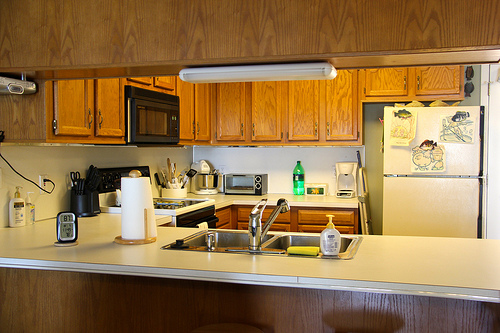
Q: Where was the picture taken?
A: It was taken at the kitchen.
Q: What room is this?
A: It is a kitchen.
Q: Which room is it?
A: It is a kitchen.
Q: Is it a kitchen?
A: Yes, it is a kitchen.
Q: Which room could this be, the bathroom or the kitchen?
A: It is the kitchen.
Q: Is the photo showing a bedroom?
A: No, the picture is showing a kitchen.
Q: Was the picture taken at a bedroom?
A: No, the picture was taken in a kitchen.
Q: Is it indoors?
A: Yes, it is indoors.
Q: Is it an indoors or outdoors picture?
A: It is indoors.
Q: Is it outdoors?
A: No, it is indoors.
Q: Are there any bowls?
A: No, there are no bowls.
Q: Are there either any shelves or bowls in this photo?
A: No, there are no bowls or shelves.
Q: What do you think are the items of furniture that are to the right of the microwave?
A: The pieces of furniture are cabinets.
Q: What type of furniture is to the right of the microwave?
A: The pieces of furniture are cabinets.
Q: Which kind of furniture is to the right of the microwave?
A: The pieces of furniture are cabinets.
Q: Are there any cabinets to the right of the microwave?
A: Yes, there are cabinets to the right of the microwave.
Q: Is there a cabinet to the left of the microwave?
A: No, the cabinets are to the right of the microwave.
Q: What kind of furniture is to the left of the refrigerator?
A: The pieces of furniture are cabinets.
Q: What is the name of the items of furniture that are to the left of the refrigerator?
A: The pieces of furniture are cabinets.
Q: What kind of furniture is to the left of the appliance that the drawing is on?
A: The pieces of furniture are cabinets.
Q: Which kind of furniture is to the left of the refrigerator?
A: The pieces of furniture are cabinets.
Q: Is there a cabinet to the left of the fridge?
A: Yes, there are cabinets to the left of the fridge.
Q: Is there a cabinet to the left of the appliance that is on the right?
A: Yes, there are cabinets to the left of the fridge.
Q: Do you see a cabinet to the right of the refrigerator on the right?
A: No, the cabinets are to the left of the fridge.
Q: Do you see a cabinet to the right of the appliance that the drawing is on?
A: No, the cabinets are to the left of the fridge.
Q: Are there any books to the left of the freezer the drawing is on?
A: No, there are cabinets to the left of the freezer.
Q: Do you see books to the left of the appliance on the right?
A: No, there are cabinets to the left of the freezer.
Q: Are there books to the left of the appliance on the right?
A: No, there are cabinets to the left of the freezer.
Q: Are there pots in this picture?
A: No, there are no pots.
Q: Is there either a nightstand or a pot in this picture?
A: No, there are no pots or nightstands.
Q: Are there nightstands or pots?
A: No, there are no pots or nightstands.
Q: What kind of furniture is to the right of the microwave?
A: The pieces of furniture are cabinets.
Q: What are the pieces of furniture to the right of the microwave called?
A: The pieces of furniture are cabinets.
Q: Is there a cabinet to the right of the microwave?
A: Yes, there are cabinets to the right of the microwave.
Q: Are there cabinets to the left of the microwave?
A: No, the cabinets are to the right of the microwave.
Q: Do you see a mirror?
A: No, there are no mirrors.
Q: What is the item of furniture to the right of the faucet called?
A: The piece of furniture is a drawer.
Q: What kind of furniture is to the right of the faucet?
A: The piece of furniture is a drawer.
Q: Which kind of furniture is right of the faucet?
A: The piece of furniture is a drawer.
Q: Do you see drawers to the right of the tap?
A: Yes, there is a drawer to the right of the tap.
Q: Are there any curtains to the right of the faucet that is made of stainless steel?
A: No, there is a drawer to the right of the faucet.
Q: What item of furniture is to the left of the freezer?
A: The piece of furniture is a drawer.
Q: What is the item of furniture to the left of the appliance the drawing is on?
A: The piece of furniture is a drawer.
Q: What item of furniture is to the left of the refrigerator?
A: The piece of furniture is a drawer.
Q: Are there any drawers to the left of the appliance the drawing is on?
A: Yes, there is a drawer to the left of the freezer.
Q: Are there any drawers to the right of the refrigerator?
A: No, the drawer is to the left of the refrigerator.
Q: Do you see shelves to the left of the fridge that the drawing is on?
A: No, there is a drawer to the left of the fridge.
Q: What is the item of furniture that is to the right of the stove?
A: The piece of furniture is a drawer.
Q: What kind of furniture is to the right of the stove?
A: The piece of furniture is a drawer.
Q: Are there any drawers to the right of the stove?
A: Yes, there is a drawer to the right of the stove.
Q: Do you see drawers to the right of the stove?
A: Yes, there is a drawer to the right of the stove.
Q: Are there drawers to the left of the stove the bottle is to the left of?
A: No, the drawer is to the right of the stove.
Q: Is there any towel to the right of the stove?
A: No, there is a drawer to the right of the stove.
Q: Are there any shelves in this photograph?
A: No, there are no shelves.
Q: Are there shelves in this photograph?
A: No, there are no shelves.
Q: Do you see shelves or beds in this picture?
A: No, there are no shelves or beds.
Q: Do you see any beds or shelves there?
A: No, there are no shelves or beds.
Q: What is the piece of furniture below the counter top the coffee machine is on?
A: The piece of furniture is a drawer.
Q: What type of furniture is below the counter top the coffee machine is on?
A: The piece of furniture is a drawer.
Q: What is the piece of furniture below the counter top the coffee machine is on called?
A: The piece of furniture is a drawer.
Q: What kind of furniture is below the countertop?
A: The piece of furniture is a drawer.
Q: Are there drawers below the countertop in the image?
A: Yes, there is a drawer below the countertop.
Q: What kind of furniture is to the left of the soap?
A: The piece of furniture is a drawer.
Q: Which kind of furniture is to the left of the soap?
A: The piece of furniture is a drawer.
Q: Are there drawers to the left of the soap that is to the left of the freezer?
A: Yes, there is a drawer to the left of the soap.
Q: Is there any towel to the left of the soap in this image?
A: No, there is a drawer to the left of the soap.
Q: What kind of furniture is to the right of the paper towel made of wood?
A: The piece of furniture is a drawer.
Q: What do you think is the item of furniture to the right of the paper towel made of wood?
A: The piece of furniture is a drawer.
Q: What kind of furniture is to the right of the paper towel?
A: The piece of furniture is a drawer.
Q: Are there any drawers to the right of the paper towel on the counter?
A: Yes, there is a drawer to the right of the paper towel.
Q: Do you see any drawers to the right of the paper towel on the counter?
A: Yes, there is a drawer to the right of the paper towel.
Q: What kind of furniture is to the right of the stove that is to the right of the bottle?
A: The piece of furniture is a drawer.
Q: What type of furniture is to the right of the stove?
A: The piece of furniture is a drawer.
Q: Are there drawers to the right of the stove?
A: Yes, there is a drawer to the right of the stove.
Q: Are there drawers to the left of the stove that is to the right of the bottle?
A: No, the drawer is to the right of the stove.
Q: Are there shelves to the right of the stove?
A: No, there is a drawer to the right of the stove.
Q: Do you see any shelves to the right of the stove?
A: No, there is a drawer to the right of the stove.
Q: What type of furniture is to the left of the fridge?
A: The piece of furniture is a drawer.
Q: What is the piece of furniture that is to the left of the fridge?
A: The piece of furniture is a drawer.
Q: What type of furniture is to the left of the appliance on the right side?
A: The piece of furniture is a drawer.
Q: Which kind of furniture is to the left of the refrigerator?
A: The piece of furniture is a drawer.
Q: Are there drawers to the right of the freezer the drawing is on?
A: No, the drawer is to the left of the fridge.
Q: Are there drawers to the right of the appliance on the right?
A: No, the drawer is to the left of the fridge.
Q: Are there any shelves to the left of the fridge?
A: No, there is a drawer to the left of the fridge.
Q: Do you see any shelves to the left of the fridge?
A: No, there is a drawer to the left of the fridge.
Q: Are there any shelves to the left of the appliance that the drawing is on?
A: No, there is a drawer to the left of the fridge.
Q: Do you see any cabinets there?
A: Yes, there is a cabinet.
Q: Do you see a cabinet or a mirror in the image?
A: Yes, there is a cabinet.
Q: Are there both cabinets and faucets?
A: Yes, there are both a cabinet and a faucet.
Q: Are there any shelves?
A: No, there are no shelves.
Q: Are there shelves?
A: No, there are no shelves.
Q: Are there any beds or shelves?
A: No, there are no shelves or beds.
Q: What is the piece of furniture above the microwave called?
A: The piece of furniture is a cabinet.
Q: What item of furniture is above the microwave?
A: The piece of furniture is a cabinet.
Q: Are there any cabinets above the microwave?
A: Yes, there is a cabinet above the microwave.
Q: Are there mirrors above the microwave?
A: No, there is a cabinet above the microwave.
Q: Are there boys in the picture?
A: No, there are no boys.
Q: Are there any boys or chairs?
A: No, there are no boys or chairs.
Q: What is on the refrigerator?
A: The drawing is on the refrigerator.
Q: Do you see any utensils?
A: Yes, there are utensils.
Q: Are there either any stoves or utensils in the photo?
A: Yes, there are utensils.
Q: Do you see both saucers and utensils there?
A: No, there are utensils but no saucers.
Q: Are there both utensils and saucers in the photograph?
A: No, there are utensils but no saucers.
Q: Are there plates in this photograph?
A: No, there are no plates.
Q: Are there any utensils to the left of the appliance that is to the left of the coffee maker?
A: Yes, there are utensils to the left of the appliance.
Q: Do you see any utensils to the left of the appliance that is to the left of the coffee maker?
A: Yes, there are utensils to the left of the appliance.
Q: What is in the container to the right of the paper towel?
A: The utensils are in the container.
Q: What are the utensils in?
A: The utensils are in the container.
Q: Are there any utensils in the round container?
A: Yes, there are utensils in the container.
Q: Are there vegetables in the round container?
A: No, there are utensils in the container.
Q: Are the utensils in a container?
A: Yes, the utensils are in a container.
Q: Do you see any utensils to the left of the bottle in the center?
A: Yes, there are utensils to the left of the bottle.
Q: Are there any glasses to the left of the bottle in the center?
A: No, there are utensils to the left of the bottle.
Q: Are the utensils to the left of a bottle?
A: Yes, the utensils are to the left of a bottle.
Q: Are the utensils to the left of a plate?
A: No, the utensils are to the left of a bottle.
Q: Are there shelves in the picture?
A: No, there are no shelves.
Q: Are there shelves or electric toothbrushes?
A: No, there are no shelves or electric toothbrushes.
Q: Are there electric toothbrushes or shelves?
A: No, there are no shelves or electric toothbrushes.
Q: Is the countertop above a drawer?
A: Yes, the countertop is above a drawer.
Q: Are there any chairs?
A: No, there are no chairs.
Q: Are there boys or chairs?
A: No, there are no chairs or boys.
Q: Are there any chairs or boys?
A: No, there are no chairs or boys.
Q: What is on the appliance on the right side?
A: The drawing is on the refrigerator.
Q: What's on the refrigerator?
A: The drawing is on the refrigerator.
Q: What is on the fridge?
A: The drawing is on the fridge.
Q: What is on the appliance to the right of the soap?
A: The drawing is on the fridge.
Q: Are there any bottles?
A: Yes, there is a bottle.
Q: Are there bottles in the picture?
A: Yes, there is a bottle.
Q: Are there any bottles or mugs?
A: Yes, there is a bottle.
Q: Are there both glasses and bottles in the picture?
A: No, there is a bottle but no glasses.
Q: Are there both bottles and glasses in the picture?
A: No, there is a bottle but no glasses.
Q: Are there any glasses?
A: No, there are no glasses.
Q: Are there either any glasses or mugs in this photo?
A: No, there are no glasses or mugs.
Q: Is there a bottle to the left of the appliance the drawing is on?
A: Yes, there is a bottle to the left of the refrigerator.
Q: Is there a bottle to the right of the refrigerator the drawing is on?
A: No, the bottle is to the left of the freezer.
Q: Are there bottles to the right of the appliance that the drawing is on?
A: No, the bottle is to the left of the freezer.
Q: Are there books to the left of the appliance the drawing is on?
A: No, there is a bottle to the left of the fridge.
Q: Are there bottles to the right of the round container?
A: Yes, there is a bottle to the right of the container.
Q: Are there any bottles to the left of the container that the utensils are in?
A: No, the bottle is to the right of the container.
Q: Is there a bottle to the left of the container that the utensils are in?
A: No, the bottle is to the right of the container.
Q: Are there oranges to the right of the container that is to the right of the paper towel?
A: No, there is a bottle to the right of the container.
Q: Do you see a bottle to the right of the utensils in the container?
A: Yes, there is a bottle to the right of the utensils.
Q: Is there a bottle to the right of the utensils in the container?
A: Yes, there is a bottle to the right of the utensils.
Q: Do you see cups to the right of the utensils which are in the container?
A: No, there is a bottle to the right of the utensils.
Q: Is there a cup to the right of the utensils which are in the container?
A: No, there is a bottle to the right of the utensils.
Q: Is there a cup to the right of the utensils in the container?
A: No, there is a bottle to the right of the utensils.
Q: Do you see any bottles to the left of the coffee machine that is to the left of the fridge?
A: Yes, there is a bottle to the left of the coffee machine.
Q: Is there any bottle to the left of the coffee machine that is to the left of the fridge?
A: Yes, there is a bottle to the left of the coffee machine.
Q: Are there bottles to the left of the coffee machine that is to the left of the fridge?
A: Yes, there is a bottle to the left of the coffee machine.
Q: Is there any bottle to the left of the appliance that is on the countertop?
A: Yes, there is a bottle to the left of the coffee machine.